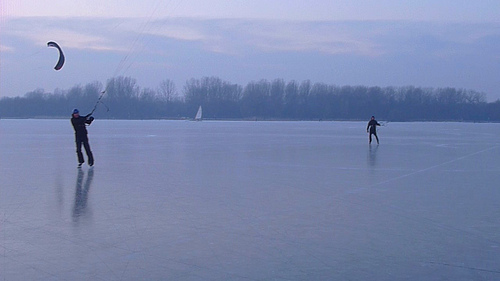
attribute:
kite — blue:
[41, 37, 73, 75]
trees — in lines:
[1, 71, 493, 131]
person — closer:
[70, 102, 97, 165]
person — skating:
[362, 112, 383, 147]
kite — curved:
[11, 27, 92, 87]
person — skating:
[366, 115, 384, 145]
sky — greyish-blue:
[0, 0, 499, 86]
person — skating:
[61, 100, 99, 175]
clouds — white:
[84, 9, 430, 41]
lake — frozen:
[116, 121, 366, 271]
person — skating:
[55, 105, 135, 217]